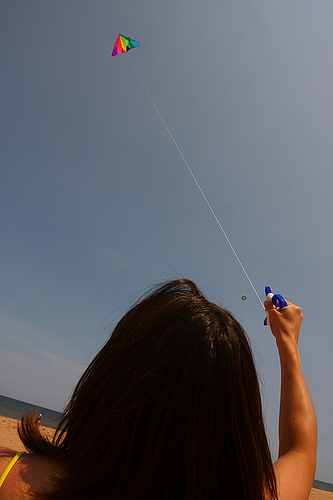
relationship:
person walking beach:
[0, 275, 318, 499] [0, 352, 77, 461]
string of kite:
[120, 52, 265, 310] [110, 32, 141, 56]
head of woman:
[81, 226, 289, 428] [0, 215, 326, 499]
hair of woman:
[59, 250, 303, 455] [0, 215, 326, 499]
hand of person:
[261, 290, 310, 345] [0, 275, 318, 499]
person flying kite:
[0, 275, 318, 499] [107, 27, 141, 62]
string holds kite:
[120, 52, 324, 287] [112, 30, 139, 59]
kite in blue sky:
[239, 295, 248, 302] [0, 0, 332, 487]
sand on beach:
[1, 417, 18, 450] [5, 417, 34, 436]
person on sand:
[125, 301, 270, 460] [0, 417, 332, 499]